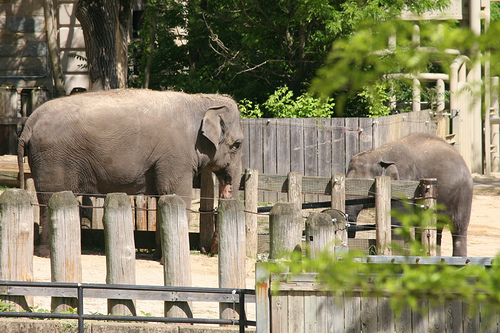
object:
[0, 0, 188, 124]
wall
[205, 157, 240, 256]
trunk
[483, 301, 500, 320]
leaves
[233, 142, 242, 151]
eye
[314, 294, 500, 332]
shadow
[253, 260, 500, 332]
wall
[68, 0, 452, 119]
tree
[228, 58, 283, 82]
branch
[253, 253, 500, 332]
fence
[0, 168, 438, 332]
fence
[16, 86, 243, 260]
elephant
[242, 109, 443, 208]
fence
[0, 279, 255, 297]
railing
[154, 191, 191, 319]
fence post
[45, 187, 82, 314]
fence post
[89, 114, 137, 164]
skin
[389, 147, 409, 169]
skin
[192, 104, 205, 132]
skin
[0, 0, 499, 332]
zoo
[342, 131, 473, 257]
elephant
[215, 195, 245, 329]
post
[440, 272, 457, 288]
leaves